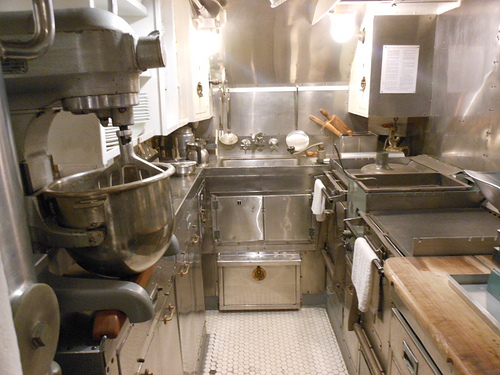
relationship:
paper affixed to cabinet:
[379, 45, 420, 96] [346, 11, 428, 121]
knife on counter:
[306, 107, 350, 138] [203, 142, 425, 171]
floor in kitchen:
[204, 306, 349, 373] [1, 0, 498, 375]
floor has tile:
[204, 306, 349, 373] [209, 332, 215, 337]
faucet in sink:
[251, 130, 262, 147] [219, 155, 311, 167]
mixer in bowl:
[21, 0, 165, 195] [37, 152, 184, 282]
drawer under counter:
[390, 304, 445, 374] [383, 250, 497, 374]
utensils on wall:
[213, 84, 226, 134] [200, 5, 363, 150]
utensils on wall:
[222, 86, 235, 131] [200, 5, 363, 150]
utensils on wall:
[291, 84, 303, 128] [200, 5, 363, 150]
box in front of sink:
[213, 248, 303, 312] [350, 164, 470, 193]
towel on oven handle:
[350, 235, 382, 315] [342, 213, 374, 241]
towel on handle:
[350, 235, 382, 315] [342, 217, 384, 273]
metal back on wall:
[423, 0, 498, 173] [421, 0, 498, 172]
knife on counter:
[308, 109, 350, 138] [310, 112, 491, 334]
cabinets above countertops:
[121, 0, 215, 129] [171, 169, 200, 218]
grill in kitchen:
[351, 206, 498, 251] [1, 0, 498, 375]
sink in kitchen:
[217, 156, 304, 166] [1, 0, 498, 375]